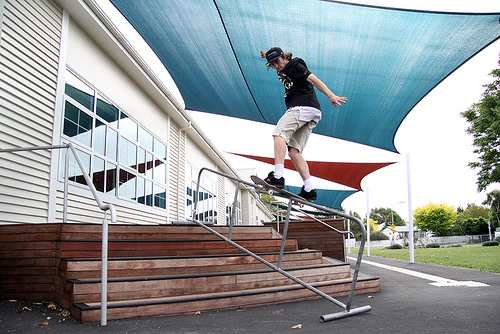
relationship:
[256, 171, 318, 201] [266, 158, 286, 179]
shoes with sock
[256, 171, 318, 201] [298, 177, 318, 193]
shoes with sock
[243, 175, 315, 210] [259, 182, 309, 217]
skateboard with wheels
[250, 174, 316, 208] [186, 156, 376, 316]
skateboard no a railing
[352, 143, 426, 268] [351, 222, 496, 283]
poles along grass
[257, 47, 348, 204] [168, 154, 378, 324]
man skateboarding on a rail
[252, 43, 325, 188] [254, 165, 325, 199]
man wearing shoes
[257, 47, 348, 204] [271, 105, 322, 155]
man wearing khaki shorts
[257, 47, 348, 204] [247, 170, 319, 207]
man riding on skateboard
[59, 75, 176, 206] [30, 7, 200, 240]
window on building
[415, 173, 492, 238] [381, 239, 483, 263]
tree in grass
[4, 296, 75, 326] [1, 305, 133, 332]
leaves on ground